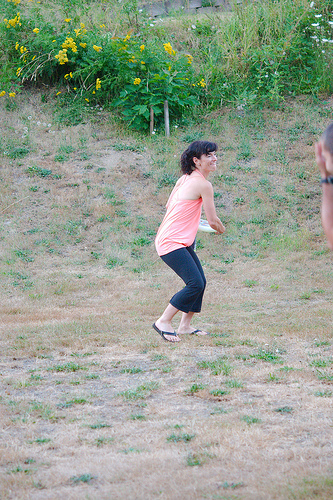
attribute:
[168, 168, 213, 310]
girl — standing, whiet, white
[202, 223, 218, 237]
frisbee — white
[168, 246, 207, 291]
pants — black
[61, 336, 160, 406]
grass — green